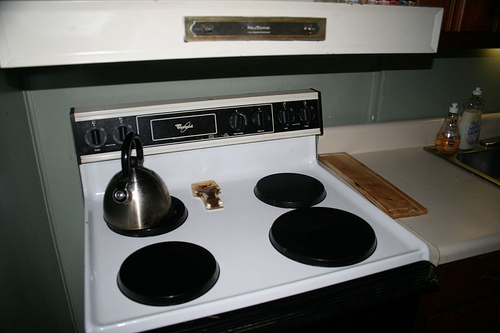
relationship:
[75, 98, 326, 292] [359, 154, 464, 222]
stove near counter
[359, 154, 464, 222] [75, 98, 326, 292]
counter near stove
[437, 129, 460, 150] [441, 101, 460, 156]
soap in bottle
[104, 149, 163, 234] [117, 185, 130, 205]
kettle has spout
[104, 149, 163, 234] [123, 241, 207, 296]
kettle on burner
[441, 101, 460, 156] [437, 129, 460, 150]
bottle has soap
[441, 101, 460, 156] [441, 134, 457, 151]
bottle has bubbles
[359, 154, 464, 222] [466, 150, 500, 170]
counter near sink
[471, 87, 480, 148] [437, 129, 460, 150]
bottle has soap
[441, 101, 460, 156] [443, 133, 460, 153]
bottle has oil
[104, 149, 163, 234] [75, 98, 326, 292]
kettle on stove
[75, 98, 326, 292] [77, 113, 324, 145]
stove has control panel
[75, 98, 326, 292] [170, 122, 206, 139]
stove has name brand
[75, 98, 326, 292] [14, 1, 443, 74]
stove has ventilation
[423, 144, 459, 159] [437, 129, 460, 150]
tray has soap